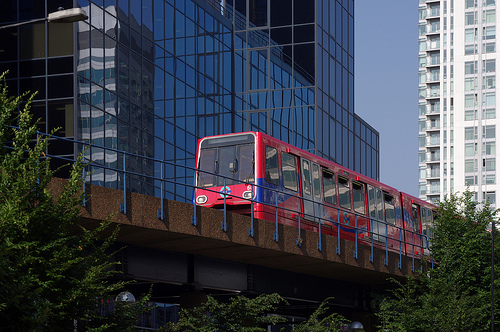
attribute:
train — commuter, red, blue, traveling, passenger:
[186, 128, 500, 273]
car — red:
[189, 129, 408, 259]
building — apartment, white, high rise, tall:
[413, 1, 499, 239]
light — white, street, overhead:
[45, 5, 89, 27]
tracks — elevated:
[1, 166, 500, 290]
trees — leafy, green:
[375, 189, 499, 332]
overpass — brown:
[1, 118, 499, 315]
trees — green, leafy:
[163, 287, 350, 332]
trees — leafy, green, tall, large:
[1, 65, 165, 331]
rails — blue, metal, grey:
[0, 119, 499, 283]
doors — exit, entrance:
[296, 153, 328, 228]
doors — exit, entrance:
[365, 178, 391, 244]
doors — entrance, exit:
[418, 201, 441, 260]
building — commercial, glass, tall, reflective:
[1, 1, 390, 331]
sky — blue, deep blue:
[351, 1, 428, 201]